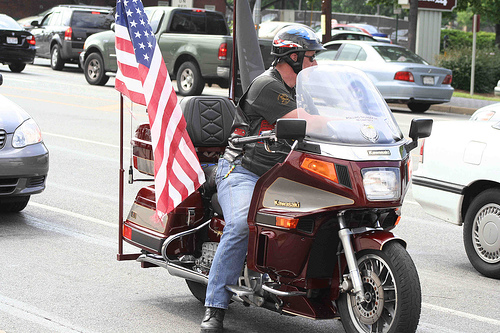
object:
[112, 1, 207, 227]
flag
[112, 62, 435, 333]
motorcycle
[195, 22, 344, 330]
man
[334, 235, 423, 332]
wheel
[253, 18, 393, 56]
vehicles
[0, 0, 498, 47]
background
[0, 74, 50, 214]
car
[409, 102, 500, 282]
car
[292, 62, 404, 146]
windshield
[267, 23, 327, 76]
helmet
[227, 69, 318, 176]
jacket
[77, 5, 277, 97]
pick-up truck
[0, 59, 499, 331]
road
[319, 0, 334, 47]
post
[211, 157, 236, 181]
key ring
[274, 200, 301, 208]
lettering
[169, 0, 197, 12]
sign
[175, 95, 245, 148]
seat back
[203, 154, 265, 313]
jeans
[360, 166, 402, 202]
headlight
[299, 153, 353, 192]
turn signal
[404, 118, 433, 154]
left mirror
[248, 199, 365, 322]
left front fender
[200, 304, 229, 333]
shoe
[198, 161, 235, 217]
seat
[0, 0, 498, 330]
traffic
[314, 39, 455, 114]
car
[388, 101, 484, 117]
curb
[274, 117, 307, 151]
mirrors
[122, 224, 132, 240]
reflector